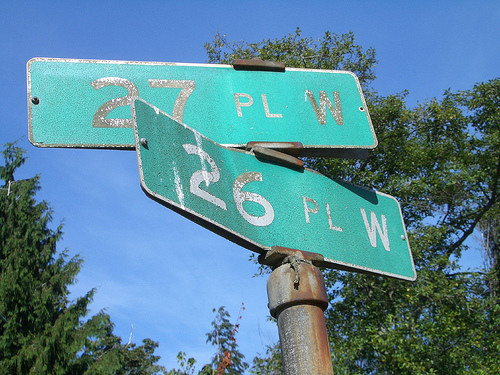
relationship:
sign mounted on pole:
[128, 99, 423, 280] [259, 245, 342, 373]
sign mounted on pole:
[25, 54, 379, 150] [259, 245, 342, 373]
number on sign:
[234, 167, 274, 235] [117, 121, 437, 293]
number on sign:
[151, 75, 204, 132] [25, 54, 379, 150]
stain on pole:
[299, 266, 335, 371] [263, 252, 344, 361]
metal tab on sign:
[260, 245, 322, 268] [128, 99, 423, 280]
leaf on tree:
[449, 247, 461, 259] [0, 138, 167, 373]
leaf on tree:
[55, 230, 64, 242] [0, 138, 167, 373]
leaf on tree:
[39, 207, 46, 215] [197, 25, 497, 373]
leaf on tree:
[377, 318, 417, 353] [355, 288, 467, 355]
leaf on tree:
[86, 347, 96, 360] [1, 139, 148, 374]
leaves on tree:
[376, 93, 498, 209] [1, 139, 148, 374]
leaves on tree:
[12, 191, 69, 308] [2, 141, 123, 341]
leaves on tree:
[431, 270, 465, 325] [202, 36, 496, 342]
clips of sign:
[260, 131, 325, 181] [16, 40, 403, 169]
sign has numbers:
[13, 41, 393, 161] [85, 66, 271, 230]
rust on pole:
[270, 245, 326, 369] [265, 249, 330, 371]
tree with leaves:
[0, 138, 167, 373] [21, 267, 35, 281]